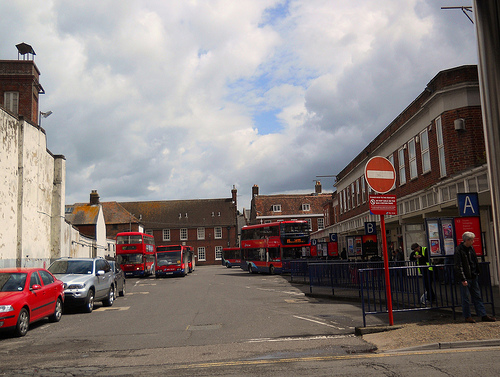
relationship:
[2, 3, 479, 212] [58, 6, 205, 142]
sky filled with clouds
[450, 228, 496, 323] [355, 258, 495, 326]
man standing beside railing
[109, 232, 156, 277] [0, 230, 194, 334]
vehicle in row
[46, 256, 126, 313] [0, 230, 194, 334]
vehicle in row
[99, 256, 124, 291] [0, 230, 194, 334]
vehicle in row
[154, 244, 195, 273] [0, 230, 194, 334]
vehicle in row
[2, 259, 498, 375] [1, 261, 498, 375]
ground covered in pavement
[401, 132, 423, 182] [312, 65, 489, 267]
window of a building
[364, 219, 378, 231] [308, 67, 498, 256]
b sign on building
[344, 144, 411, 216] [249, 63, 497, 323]
sign on building